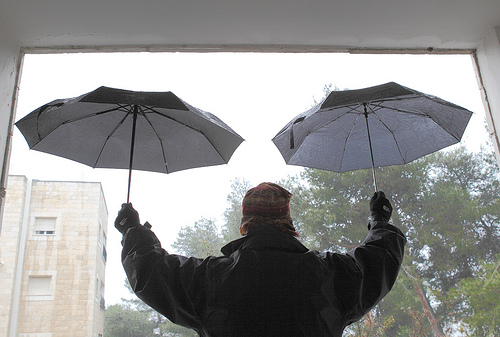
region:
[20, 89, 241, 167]
The umbrella on the left.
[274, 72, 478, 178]
The umbrella on the right.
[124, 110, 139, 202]
The pole of the umbrella on the left.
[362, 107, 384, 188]
The pole of the umbrella on the right.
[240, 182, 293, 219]
The hat the person is wearing.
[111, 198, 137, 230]
The glove on the person's left hand.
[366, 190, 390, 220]
The glove on the person's right hand.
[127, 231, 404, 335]
The jacket the guy is wearing.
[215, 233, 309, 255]
The collar of the jacket.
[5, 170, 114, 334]
The building on the left.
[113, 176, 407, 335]
Man holding two black umbrellas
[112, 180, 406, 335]
Man wearing black jacket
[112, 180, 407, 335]
Man wearing black gloves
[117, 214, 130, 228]
The North Face logo on black glove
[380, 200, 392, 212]
The North Face logo on black glove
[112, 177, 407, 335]
Man wearing red and brown beanie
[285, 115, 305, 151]
Black strap on umbrella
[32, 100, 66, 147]
Black strap on umbrella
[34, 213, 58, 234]
Window on large building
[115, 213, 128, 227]
The North Face logo on black glove is white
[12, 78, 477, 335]
Man holding two umbrellas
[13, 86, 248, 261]
Black umbrella on left hand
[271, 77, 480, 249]
Black umbrella on right hand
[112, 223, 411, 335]
black jacket worn by man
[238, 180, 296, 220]
red bonnet on man'd head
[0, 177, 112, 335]
Peach building next to a tree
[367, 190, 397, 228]
black glove worn on the right hand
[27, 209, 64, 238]
partially opened window on top floor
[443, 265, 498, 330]
Green leaves of a tree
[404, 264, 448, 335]
brown trunk of a tree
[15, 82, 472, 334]
A man holds two umbrellas.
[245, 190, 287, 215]
The man wears a knitted cap.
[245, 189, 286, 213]
The cap is patterned.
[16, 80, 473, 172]
The umbrellas are black.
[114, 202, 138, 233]
The man wears gloves.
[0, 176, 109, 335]
A building is in the background.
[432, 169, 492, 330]
Trees are in the background.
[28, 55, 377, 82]
The sky is overcast.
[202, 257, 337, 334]
The man wears a jacket.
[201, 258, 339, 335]
The jacket is black.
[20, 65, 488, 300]
person holding out two umbrellas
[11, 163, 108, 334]
building behind the figure of the man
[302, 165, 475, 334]
trees behind the person's arm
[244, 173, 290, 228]
hat on the person's head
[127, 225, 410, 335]
black jacket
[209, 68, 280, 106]
white sky above the person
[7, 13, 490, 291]
doorway of the building the person is standing in front of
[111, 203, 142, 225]
glove on the person's hand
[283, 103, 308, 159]
strap hanging down from the umbrella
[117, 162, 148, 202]
pole of the umbrella